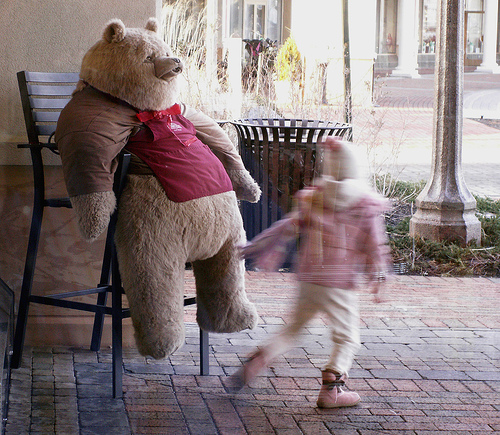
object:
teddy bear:
[57, 17, 261, 362]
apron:
[125, 102, 235, 202]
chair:
[0, 69, 216, 399]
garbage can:
[228, 116, 352, 274]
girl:
[229, 135, 391, 408]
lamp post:
[406, 0, 484, 246]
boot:
[313, 373, 362, 410]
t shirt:
[52, 81, 248, 200]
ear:
[102, 18, 128, 44]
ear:
[142, 16, 160, 33]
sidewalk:
[0, 268, 498, 434]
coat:
[258, 175, 388, 291]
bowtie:
[135, 104, 182, 126]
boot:
[231, 348, 270, 389]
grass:
[376, 171, 500, 279]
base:
[393, 208, 493, 249]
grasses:
[157, 1, 416, 201]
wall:
[1, 1, 165, 351]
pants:
[260, 283, 372, 378]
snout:
[154, 56, 184, 82]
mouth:
[170, 66, 183, 75]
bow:
[323, 378, 345, 394]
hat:
[321, 133, 363, 182]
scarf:
[235, 193, 313, 275]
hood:
[317, 174, 368, 213]